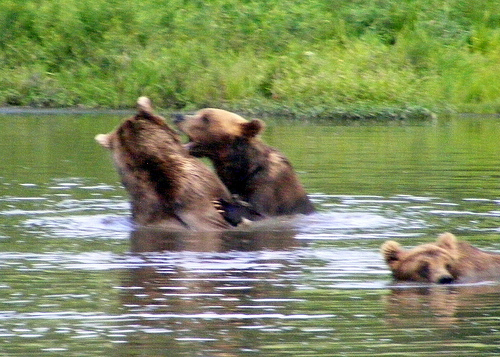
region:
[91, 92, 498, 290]
three bears playing in the water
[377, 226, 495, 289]
a bear swimming in the river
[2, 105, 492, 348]
the river water is calm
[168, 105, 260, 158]
the bear's mouth is open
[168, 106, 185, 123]
the bear has a black nose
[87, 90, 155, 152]
the bear has white ears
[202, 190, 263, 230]
long claws on the bears paw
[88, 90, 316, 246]
the fur on the bears is black and brown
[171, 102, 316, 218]
the bear is a baby grizzly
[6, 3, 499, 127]
green bushes are growing on the river bank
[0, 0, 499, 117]
A blurred image of green trees and bushes in the background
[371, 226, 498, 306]
A brown bear submerged under water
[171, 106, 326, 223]
A brown bear with its paw on another brown bear attempting to bite it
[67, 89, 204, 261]
A brown bear in water leaning to the side to avoid being bitten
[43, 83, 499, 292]
Three brown bears in the water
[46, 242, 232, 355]
Ripples in the water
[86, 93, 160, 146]
The brown bears ears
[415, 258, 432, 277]
The bear's eye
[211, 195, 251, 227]
The bear's paw with claws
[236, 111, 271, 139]
The bear's ear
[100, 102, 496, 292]
three bears in water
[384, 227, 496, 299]
partially submerged brown bear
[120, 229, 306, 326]
reflection of bears in water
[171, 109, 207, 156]
open mouth of bear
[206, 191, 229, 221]
claws of bear on other bear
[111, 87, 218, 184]
bear leaning away from other bear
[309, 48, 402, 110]
green vegetation on bank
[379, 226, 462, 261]
two ears of beer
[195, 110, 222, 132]
eye on bear's head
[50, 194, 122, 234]
ripples from moving bears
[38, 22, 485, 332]
a blurry nature picture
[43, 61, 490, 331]
a few animals playing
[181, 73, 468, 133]
a plant covered bank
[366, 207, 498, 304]
a mostly submerged bear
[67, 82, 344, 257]
a few brown bears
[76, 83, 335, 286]
two bears standing up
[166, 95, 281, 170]
a bear with it's mouth open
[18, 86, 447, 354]
a natural body of water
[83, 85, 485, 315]
some wild bears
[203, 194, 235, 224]
long bear claws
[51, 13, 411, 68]
these are vegetations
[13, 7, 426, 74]
the vegetation are green in color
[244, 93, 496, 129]
this is river bank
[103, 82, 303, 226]
these are bears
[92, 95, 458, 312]
the bears are in the water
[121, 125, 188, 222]
this is fur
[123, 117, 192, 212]
the fur is brown with black spot on it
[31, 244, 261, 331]
this is river water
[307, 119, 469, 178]
the water appears green in color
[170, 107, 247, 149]
the bear has opened its mouth